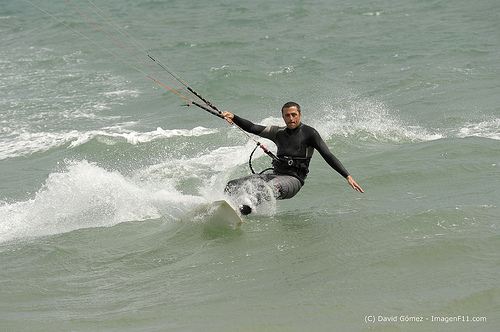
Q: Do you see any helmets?
A: No, there are no helmets.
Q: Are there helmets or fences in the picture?
A: No, there are no helmets or fences.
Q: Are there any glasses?
A: No, there are no glasses.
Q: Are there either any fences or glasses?
A: No, there are no glasses or fences.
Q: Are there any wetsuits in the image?
A: Yes, there is a wetsuit.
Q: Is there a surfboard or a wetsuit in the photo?
A: Yes, there is a wetsuit.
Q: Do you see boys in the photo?
A: No, there are no boys.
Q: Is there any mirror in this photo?
A: No, there are no mirrors.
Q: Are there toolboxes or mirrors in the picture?
A: No, there are no mirrors or toolboxes.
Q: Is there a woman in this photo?
A: No, there are no women.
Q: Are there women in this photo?
A: No, there are no women.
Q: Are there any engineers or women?
A: No, there are no women or engineers.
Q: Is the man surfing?
A: Yes, the man is surfing.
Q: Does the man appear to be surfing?
A: Yes, the man is surfing.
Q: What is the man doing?
A: The man is surfing.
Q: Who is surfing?
A: The man is surfing.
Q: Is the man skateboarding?
A: No, the man is surfing.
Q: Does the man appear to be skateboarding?
A: No, the man is surfing.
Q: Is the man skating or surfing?
A: The man is surfing.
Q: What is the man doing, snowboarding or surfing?
A: The man is surfing.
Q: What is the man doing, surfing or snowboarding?
A: The man is surfing.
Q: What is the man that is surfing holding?
A: The man is holding the wire.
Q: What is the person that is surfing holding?
A: The man is holding the wire.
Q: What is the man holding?
A: The man is holding the wire.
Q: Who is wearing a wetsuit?
A: The man is wearing a wetsuit.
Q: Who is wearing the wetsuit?
A: The man is wearing a wetsuit.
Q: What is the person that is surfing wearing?
A: The man is wearing a wetsuit.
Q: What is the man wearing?
A: The man is wearing a wetsuit.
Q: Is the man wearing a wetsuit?
A: Yes, the man is wearing a wetsuit.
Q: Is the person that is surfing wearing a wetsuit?
A: Yes, the man is wearing a wetsuit.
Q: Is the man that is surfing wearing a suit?
A: No, the man is wearing a wetsuit.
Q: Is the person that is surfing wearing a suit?
A: No, the man is wearing a wetsuit.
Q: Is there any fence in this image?
A: No, there are no fences.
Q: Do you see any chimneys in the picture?
A: No, there are no chimneys.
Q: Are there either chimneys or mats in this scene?
A: No, there are no chimneys or mats.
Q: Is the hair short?
A: Yes, the hair is short.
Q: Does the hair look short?
A: Yes, the hair is short.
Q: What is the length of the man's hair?
A: The hair is short.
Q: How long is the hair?
A: The hair is short.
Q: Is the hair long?
A: No, the hair is short.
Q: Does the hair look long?
A: No, the hair is short.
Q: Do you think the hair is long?
A: No, the hair is short.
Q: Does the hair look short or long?
A: The hair is short.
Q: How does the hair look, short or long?
A: The hair is short.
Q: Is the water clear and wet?
A: Yes, the water is clear and wet.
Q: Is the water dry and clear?
A: No, the water is clear but wet.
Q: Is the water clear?
A: Yes, the water is clear.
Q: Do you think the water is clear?
A: Yes, the water is clear.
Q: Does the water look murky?
A: No, the water is clear.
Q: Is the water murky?
A: No, the water is clear.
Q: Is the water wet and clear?
A: Yes, the water is wet and clear.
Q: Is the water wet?
A: Yes, the water is wet.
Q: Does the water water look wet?
A: Yes, the water is wet.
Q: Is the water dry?
A: No, the water is wet.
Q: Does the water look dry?
A: No, the water is wet.